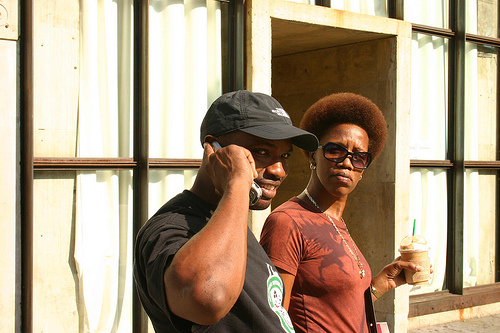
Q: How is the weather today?
A: It is sunny.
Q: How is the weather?
A: It is sunny.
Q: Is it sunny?
A: Yes, it is sunny.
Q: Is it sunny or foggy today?
A: It is sunny.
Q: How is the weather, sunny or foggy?
A: It is sunny.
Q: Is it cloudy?
A: No, it is sunny.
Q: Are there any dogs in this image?
A: No, there are no dogs.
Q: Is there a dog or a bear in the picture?
A: No, there are no dogs or bears.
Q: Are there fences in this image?
A: No, there are no fences.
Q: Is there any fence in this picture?
A: No, there are no fences.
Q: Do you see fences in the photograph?
A: No, there are no fences.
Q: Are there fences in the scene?
A: No, there are no fences.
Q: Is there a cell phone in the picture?
A: Yes, there is a cell phone.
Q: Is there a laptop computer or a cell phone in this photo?
A: Yes, there is a cell phone.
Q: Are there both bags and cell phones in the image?
A: No, there is a cell phone but no bags.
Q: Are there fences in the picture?
A: No, there are no fences.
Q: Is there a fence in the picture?
A: No, there are no fences.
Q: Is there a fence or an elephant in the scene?
A: No, there are no fences or elephants.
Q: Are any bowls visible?
A: No, there are no bowls.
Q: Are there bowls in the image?
A: No, there are no bowls.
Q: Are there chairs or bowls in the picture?
A: No, there are no bowls or chairs.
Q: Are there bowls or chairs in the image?
A: No, there are no bowls or chairs.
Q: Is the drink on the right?
A: Yes, the drink is on the right of the image.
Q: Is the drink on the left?
A: No, the drink is on the right of the image.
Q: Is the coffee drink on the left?
A: No, the drink is on the right of the image.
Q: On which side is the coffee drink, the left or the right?
A: The drink is on the right of the image.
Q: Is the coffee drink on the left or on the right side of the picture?
A: The drink is on the right of the image.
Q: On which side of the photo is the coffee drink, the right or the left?
A: The drink is on the right of the image.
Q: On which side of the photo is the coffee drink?
A: The drink is on the right of the image.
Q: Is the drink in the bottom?
A: Yes, the drink is in the bottom of the image.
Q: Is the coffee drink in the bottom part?
A: Yes, the drink is in the bottom of the image.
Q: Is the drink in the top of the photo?
A: No, the drink is in the bottom of the image.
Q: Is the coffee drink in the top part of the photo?
A: No, the drink is in the bottom of the image.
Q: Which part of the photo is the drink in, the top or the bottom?
A: The drink is in the bottom of the image.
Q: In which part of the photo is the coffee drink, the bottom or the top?
A: The drink is in the bottom of the image.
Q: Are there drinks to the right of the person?
A: Yes, there is a drink to the right of the person.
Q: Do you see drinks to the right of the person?
A: Yes, there is a drink to the right of the person.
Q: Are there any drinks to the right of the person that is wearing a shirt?
A: Yes, there is a drink to the right of the person.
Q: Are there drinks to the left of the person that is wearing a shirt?
A: No, the drink is to the right of the person.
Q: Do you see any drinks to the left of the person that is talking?
A: No, the drink is to the right of the person.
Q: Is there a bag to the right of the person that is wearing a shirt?
A: No, there is a drink to the right of the person.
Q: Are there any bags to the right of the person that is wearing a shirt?
A: No, there is a drink to the right of the person.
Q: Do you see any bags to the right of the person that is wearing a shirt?
A: No, there is a drink to the right of the person.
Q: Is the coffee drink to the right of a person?
A: Yes, the drink is to the right of a person.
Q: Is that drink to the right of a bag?
A: No, the drink is to the right of a person.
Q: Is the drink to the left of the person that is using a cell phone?
A: No, the drink is to the right of the person.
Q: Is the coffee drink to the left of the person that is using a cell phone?
A: No, the drink is to the right of the person.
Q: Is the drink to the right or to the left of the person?
A: The drink is to the right of the person.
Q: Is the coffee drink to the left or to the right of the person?
A: The drink is to the right of the person.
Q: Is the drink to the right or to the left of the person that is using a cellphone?
A: The drink is to the right of the person.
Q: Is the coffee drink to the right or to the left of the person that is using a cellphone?
A: The drink is to the right of the person.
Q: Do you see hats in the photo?
A: Yes, there is a hat.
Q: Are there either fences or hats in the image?
A: Yes, there is a hat.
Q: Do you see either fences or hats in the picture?
A: Yes, there is a hat.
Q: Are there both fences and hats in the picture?
A: No, there is a hat but no fences.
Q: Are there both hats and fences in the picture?
A: No, there is a hat but no fences.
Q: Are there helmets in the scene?
A: No, there are no helmets.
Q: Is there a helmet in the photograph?
A: No, there are no helmets.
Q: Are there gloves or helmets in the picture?
A: No, there are no helmets or gloves.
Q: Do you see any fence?
A: No, there are no fences.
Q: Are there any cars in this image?
A: No, there are no cars.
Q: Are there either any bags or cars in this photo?
A: No, there are no cars or bags.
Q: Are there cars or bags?
A: No, there are no cars or bags.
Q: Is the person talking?
A: Yes, the person is talking.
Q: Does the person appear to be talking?
A: Yes, the person is talking.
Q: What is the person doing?
A: The person is talking.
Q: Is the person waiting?
A: No, the person is talking.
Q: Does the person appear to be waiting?
A: No, the person is talking.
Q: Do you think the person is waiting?
A: No, the person is talking.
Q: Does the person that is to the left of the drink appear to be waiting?
A: No, the person is talking.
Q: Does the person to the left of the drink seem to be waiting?
A: No, the person is talking.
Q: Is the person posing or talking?
A: The person is talking.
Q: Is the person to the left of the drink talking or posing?
A: The person is talking.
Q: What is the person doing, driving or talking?
A: The person is talking.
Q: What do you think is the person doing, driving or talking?
A: The person is talking.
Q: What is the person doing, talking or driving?
A: The person is talking.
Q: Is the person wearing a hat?
A: Yes, the person is wearing a hat.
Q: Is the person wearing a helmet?
A: No, the person is wearing a hat.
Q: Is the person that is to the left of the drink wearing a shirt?
A: Yes, the person is wearing a shirt.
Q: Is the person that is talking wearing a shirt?
A: Yes, the person is wearing a shirt.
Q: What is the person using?
A: The person is using a cellphone.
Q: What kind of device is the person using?
A: The person is using a mobile phone.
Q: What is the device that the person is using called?
A: The device is a cell phone.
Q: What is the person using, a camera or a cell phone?
A: The person is using a cell phone.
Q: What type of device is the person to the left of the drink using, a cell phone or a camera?
A: The person is using a cell phone.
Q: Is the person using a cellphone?
A: Yes, the person is using a cellphone.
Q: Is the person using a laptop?
A: No, the person is using a cellphone.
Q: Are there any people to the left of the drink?
A: Yes, there is a person to the left of the drink.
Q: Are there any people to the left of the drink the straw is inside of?
A: Yes, there is a person to the left of the drink.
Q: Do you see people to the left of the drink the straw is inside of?
A: Yes, there is a person to the left of the drink.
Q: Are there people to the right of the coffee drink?
A: No, the person is to the left of the drink.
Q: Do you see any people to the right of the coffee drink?
A: No, the person is to the left of the drink.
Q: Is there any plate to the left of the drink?
A: No, there is a person to the left of the drink.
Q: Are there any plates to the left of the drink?
A: No, there is a person to the left of the drink.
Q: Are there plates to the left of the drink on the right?
A: No, there is a person to the left of the drink.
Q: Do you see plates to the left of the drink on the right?
A: No, there is a person to the left of the drink.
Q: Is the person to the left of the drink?
A: Yes, the person is to the left of the drink.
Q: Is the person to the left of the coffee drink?
A: Yes, the person is to the left of the drink.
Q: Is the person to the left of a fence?
A: No, the person is to the left of the drink.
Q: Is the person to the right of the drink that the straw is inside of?
A: No, the person is to the left of the drink.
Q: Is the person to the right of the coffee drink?
A: No, the person is to the left of the drink.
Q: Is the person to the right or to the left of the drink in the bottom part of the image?
A: The person is to the left of the drink.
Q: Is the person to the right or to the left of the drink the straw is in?
A: The person is to the left of the drink.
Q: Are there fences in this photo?
A: No, there are no fences.